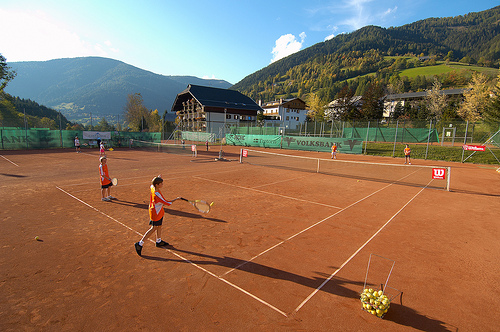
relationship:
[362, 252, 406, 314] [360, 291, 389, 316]
basket full of tennis balls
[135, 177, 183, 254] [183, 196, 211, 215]
tenni player swings racquet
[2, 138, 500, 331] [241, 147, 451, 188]
tennis court has net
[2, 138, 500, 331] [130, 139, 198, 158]
tennis court has net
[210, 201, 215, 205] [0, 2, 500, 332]
tennis ball flies through air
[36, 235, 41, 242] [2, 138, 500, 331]
tennis ball lies on tennis court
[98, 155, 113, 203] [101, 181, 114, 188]
person has black skirt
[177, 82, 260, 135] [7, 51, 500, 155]
chalet shown in distance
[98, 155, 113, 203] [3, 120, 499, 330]
person plays tennis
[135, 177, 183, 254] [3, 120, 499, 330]
person plays tennis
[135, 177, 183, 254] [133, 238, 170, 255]
person has shoes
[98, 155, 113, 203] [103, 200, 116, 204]
person has shoes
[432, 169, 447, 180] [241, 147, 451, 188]
wilson insignia attached to net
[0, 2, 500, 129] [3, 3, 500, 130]
trees on top of hills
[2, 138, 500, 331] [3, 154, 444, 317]
tennis court has lines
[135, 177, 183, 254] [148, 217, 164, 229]
person wearing shorts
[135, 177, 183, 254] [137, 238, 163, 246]
tenni player wears socks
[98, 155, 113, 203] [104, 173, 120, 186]
person has racquet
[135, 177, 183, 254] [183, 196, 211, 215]
tenni player has racquet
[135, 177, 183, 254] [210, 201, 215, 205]
tenni player hits tennis ball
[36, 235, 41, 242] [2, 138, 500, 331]
tennis ball sitting on tennis court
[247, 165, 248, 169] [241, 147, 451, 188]
tennis ball lies near net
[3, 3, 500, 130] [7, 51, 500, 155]
hills in distance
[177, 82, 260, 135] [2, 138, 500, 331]
chalet close to tennis court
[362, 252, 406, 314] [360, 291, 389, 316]
basket of tennis balls